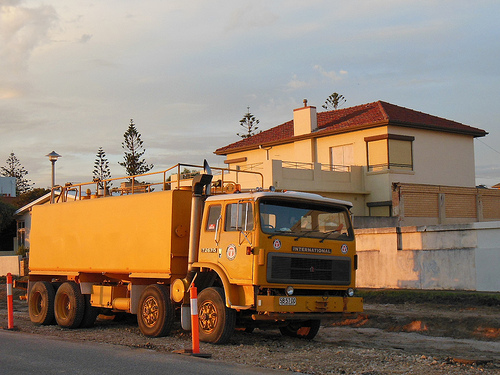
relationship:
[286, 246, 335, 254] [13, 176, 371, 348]
writing on truck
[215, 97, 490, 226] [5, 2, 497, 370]
house in photo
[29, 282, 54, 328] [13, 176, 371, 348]
wheel of truck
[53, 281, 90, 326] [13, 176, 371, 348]
back tires of truck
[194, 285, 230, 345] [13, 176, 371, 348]
wheel of truck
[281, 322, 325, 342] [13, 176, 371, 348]
wheel of truck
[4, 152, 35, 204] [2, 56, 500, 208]
tree in background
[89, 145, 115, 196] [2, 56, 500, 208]
tree in background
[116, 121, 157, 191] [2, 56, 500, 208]
tree in background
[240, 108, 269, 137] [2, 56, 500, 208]
tree in background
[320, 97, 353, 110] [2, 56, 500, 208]
tree in background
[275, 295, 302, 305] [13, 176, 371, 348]
license plate on truck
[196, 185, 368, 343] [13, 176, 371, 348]
front of truck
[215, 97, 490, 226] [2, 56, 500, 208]
house in background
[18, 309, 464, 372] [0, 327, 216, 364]
gravel near road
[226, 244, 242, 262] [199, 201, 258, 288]
logo on door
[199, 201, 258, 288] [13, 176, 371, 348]
door of truck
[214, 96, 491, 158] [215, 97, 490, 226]
roof on house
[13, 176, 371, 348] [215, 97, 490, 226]
truck near house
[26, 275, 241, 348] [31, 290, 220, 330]
tires with rims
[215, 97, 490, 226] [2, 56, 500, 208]
building in background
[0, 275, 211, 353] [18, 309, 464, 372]
pilons in gravel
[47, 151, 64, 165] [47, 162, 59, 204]
light on a pole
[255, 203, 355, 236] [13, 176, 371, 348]
window on truck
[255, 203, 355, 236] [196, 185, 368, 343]
window on front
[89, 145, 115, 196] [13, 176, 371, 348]
tree behind truck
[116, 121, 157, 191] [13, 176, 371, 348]
tree behind truck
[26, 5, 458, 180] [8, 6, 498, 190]
cloud in sky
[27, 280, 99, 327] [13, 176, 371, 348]
back tires of truck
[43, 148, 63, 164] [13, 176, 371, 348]
light behind truck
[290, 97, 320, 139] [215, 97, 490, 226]
chimney on house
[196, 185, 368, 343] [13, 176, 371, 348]
cab of truck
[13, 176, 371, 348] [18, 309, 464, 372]
truck on gravel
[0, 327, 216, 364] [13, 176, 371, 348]
road near truck